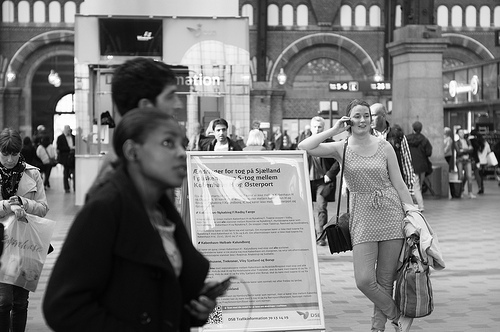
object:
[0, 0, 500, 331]
station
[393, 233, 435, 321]
purse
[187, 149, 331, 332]
sign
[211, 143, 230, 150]
shirt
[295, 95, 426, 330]
woman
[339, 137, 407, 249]
shirt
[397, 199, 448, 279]
coat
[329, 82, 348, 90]
numbers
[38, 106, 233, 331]
people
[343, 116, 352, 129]
cell phone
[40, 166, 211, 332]
jacket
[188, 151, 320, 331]
reading information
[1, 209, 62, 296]
sack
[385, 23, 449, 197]
pillar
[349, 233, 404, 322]
woman's legs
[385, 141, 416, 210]
arm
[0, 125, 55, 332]
woman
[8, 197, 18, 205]
watch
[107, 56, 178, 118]
hair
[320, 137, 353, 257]
bag on shoulder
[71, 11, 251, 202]
information booth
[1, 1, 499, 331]
background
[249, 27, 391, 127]
arches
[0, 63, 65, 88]
three ceiling lights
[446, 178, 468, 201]
trash receptacle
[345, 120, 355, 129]
phone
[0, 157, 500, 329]
ground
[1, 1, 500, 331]
picture